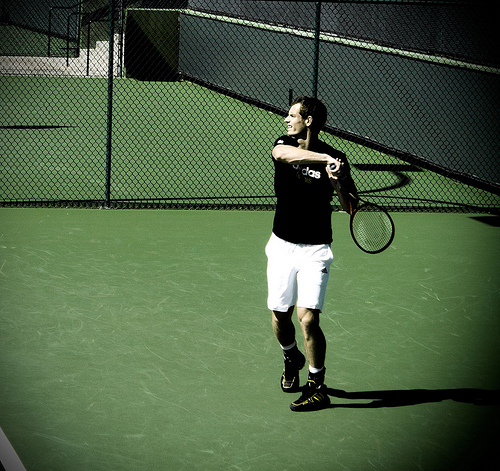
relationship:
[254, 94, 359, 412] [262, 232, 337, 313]
he has shorts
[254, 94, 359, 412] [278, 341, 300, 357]
man wearing sock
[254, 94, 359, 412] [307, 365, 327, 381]
man wearing sock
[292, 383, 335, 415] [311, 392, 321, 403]
shoe has stripe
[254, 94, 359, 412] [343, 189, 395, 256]
he has racket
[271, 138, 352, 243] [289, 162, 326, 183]
shirt made by adidas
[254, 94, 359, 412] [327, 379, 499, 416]
man casts shadow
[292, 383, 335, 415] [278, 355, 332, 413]
shoe in pair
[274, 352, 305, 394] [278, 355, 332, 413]
shoe in pair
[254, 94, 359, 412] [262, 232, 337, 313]
man in shorts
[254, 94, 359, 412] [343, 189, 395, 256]
man with racket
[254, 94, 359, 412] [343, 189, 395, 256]
man swinging racket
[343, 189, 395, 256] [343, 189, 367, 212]
racket has part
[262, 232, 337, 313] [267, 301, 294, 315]
shorts have edge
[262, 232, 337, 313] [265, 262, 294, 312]
shorts have part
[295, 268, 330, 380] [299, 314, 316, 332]
leg has part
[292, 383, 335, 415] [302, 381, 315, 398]
shoe has lace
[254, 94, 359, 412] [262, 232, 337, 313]
man wearing shorts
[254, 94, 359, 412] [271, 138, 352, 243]
man wearing t shirt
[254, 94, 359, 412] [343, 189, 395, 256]
man holding racket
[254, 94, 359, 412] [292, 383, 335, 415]
man wearing shoe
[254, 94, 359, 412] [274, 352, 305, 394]
man wearing shoe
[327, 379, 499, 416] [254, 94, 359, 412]
shadow of man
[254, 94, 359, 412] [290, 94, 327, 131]
man has hair